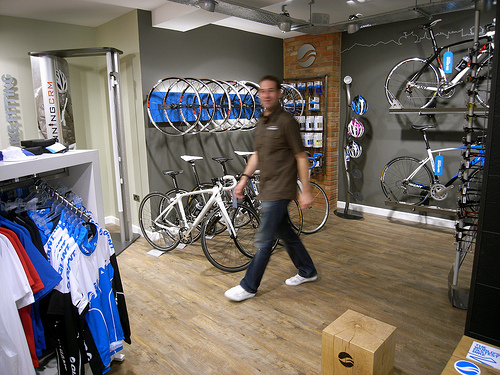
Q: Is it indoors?
A: Yes, it is indoors.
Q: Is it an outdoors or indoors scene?
A: It is indoors.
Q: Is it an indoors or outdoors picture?
A: It is indoors.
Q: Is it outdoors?
A: No, it is indoors.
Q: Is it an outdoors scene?
A: No, it is indoors.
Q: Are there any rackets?
A: No, there are no rackets.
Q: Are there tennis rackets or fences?
A: No, there are no tennis rackets or fences.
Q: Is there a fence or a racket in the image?
A: No, there are no rackets or fences.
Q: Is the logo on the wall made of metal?
A: Yes, the logo is made of metal.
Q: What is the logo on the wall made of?
A: The logo is made of metal.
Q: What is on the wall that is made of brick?
A: The logo is on the wall.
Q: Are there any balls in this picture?
A: No, there are no balls.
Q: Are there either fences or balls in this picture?
A: No, there are no balls or fences.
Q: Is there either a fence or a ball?
A: No, there are no balls or fences.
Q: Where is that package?
A: The package is on the floor.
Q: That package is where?
A: The package is on the floor.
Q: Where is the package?
A: The package is on the floor.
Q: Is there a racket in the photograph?
A: No, there are no rackets.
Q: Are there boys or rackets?
A: No, there are no rackets or boys.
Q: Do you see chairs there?
A: No, there are no chairs.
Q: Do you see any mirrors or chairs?
A: No, there are no chairs or mirrors.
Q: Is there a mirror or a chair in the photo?
A: No, there are no chairs or mirrors.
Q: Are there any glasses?
A: No, there are no glasses.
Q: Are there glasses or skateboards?
A: No, there are no glasses or skateboards.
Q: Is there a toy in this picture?
A: Yes, there is a toy.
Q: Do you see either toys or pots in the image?
A: Yes, there is a toy.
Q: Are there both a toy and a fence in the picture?
A: No, there is a toy but no fences.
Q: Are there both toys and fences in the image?
A: No, there is a toy but no fences.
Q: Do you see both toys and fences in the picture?
A: No, there is a toy but no fences.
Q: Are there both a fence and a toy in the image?
A: No, there is a toy but no fences.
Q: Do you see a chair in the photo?
A: No, there are no chairs.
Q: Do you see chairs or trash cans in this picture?
A: No, there are no chairs or trash cans.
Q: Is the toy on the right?
A: Yes, the toy is on the right of the image.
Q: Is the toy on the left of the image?
A: No, the toy is on the right of the image.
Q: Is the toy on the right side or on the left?
A: The toy is on the right of the image.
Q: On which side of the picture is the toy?
A: The toy is on the right of the image.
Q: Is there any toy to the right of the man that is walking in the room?
A: Yes, there is a toy to the right of the man.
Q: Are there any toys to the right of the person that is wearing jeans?
A: Yes, there is a toy to the right of the man.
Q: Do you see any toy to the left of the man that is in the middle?
A: No, the toy is to the right of the man.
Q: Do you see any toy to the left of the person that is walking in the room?
A: No, the toy is to the right of the man.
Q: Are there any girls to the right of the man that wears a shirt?
A: No, there is a toy to the right of the man.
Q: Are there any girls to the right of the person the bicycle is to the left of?
A: No, there is a toy to the right of the man.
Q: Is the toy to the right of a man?
A: Yes, the toy is to the right of a man.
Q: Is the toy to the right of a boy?
A: No, the toy is to the right of a man.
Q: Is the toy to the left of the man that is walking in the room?
A: No, the toy is to the right of the man.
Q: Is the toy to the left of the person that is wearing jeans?
A: No, the toy is to the right of the man.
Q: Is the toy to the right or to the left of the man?
A: The toy is to the right of the man.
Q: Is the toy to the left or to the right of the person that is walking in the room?
A: The toy is to the right of the man.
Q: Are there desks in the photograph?
A: No, there are no desks.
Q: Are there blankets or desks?
A: No, there are no desks or blankets.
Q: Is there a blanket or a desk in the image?
A: No, there are no desks or blankets.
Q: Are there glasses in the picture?
A: No, there are no glasses.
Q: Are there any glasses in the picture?
A: No, there are no glasses.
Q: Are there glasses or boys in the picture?
A: No, there are no glasses or boys.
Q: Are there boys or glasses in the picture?
A: No, there are no glasses or boys.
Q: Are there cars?
A: No, there are no cars.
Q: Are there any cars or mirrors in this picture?
A: No, there are no cars or mirrors.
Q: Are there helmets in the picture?
A: Yes, there is a helmet.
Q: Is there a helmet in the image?
A: Yes, there is a helmet.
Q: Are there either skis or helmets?
A: Yes, there is a helmet.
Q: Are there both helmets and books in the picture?
A: No, there is a helmet but no books.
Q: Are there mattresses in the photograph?
A: No, there are no mattresses.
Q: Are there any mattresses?
A: No, there are no mattresses.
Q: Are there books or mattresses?
A: No, there are no mattresses or books.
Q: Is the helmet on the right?
A: Yes, the helmet is on the right of the image.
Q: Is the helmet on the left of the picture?
A: No, the helmet is on the right of the image.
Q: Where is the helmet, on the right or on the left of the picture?
A: The helmet is on the right of the image.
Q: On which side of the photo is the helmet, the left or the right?
A: The helmet is on the right of the image.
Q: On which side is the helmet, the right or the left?
A: The helmet is on the right of the image.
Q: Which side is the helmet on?
A: The helmet is on the right of the image.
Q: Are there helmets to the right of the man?
A: Yes, there is a helmet to the right of the man.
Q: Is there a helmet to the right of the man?
A: Yes, there is a helmet to the right of the man.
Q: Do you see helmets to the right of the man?
A: Yes, there is a helmet to the right of the man.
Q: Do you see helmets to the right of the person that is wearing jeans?
A: Yes, there is a helmet to the right of the man.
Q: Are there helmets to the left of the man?
A: No, the helmet is to the right of the man.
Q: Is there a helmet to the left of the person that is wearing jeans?
A: No, the helmet is to the right of the man.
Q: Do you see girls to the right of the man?
A: No, there is a helmet to the right of the man.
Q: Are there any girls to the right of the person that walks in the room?
A: No, there is a helmet to the right of the man.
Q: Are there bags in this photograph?
A: No, there are no bags.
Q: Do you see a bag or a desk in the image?
A: No, there are no bags or desks.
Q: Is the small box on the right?
A: Yes, the box is on the right of the image.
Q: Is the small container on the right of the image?
A: Yes, the box is on the right of the image.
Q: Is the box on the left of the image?
A: No, the box is on the right of the image.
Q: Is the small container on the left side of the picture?
A: No, the box is on the right of the image.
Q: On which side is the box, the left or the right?
A: The box is on the right of the image.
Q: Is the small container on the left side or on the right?
A: The box is on the right of the image.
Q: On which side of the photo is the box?
A: The box is on the right of the image.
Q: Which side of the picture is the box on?
A: The box is on the right of the image.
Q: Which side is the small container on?
A: The box is on the right of the image.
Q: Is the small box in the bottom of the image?
A: Yes, the box is in the bottom of the image.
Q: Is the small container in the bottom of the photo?
A: Yes, the box is in the bottom of the image.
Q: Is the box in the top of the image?
A: No, the box is in the bottom of the image.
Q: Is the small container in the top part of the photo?
A: No, the box is in the bottom of the image.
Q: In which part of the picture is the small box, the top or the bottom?
A: The box is in the bottom of the image.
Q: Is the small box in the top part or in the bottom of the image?
A: The box is in the bottom of the image.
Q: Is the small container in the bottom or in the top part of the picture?
A: The box is in the bottom of the image.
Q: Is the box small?
A: Yes, the box is small.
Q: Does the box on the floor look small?
A: Yes, the box is small.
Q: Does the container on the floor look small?
A: Yes, the box is small.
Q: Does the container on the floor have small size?
A: Yes, the box is small.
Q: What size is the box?
A: The box is small.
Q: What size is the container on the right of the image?
A: The box is small.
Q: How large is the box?
A: The box is small.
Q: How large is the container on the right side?
A: The box is small.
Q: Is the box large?
A: No, the box is small.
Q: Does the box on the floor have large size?
A: No, the box is small.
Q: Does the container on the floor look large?
A: No, the box is small.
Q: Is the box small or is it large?
A: The box is small.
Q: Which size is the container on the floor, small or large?
A: The box is small.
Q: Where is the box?
A: The box is on the floor.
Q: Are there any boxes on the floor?
A: Yes, there is a box on the floor.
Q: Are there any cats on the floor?
A: No, there is a box on the floor.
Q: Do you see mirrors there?
A: No, there are no mirrors.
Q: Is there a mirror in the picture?
A: No, there are no mirrors.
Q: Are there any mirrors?
A: No, there are no mirrors.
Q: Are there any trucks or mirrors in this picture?
A: No, there are no mirrors or trucks.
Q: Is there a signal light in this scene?
A: No, there are no traffic lights.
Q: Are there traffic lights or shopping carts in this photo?
A: No, there are no traffic lights or shopping carts.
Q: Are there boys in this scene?
A: No, there are no boys.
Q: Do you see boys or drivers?
A: No, there are no boys or drivers.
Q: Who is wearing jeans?
A: The man is wearing jeans.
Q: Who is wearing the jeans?
A: The man is wearing jeans.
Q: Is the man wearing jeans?
A: Yes, the man is wearing jeans.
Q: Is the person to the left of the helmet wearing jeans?
A: Yes, the man is wearing jeans.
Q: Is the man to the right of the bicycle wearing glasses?
A: No, the man is wearing jeans.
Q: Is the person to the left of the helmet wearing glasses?
A: No, the man is wearing jeans.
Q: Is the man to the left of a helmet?
A: Yes, the man is to the left of a helmet.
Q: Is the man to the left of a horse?
A: No, the man is to the left of a helmet.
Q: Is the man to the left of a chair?
A: No, the man is to the left of a helmet.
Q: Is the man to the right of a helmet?
A: No, the man is to the left of a helmet.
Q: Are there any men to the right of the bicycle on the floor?
A: Yes, there is a man to the right of the bicycle.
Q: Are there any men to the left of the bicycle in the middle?
A: No, the man is to the right of the bicycle.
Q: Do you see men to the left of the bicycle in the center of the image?
A: No, the man is to the right of the bicycle.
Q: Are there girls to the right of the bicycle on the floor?
A: No, there is a man to the right of the bicycle.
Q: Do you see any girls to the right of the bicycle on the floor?
A: No, there is a man to the right of the bicycle.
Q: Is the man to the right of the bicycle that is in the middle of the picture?
A: Yes, the man is to the right of the bicycle.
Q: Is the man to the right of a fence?
A: No, the man is to the right of the bicycle.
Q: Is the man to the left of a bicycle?
A: No, the man is to the right of a bicycle.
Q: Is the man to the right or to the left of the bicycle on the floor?
A: The man is to the right of the bicycle.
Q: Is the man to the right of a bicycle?
A: No, the man is to the left of a bicycle.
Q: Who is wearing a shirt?
A: The man is wearing a shirt.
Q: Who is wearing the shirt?
A: The man is wearing a shirt.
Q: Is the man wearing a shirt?
A: Yes, the man is wearing a shirt.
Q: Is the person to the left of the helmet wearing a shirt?
A: Yes, the man is wearing a shirt.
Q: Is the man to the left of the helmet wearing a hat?
A: No, the man is wearing a shirt.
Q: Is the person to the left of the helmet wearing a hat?
A: No, the man is wearing a shirt.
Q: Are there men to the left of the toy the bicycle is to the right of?
A: Yes, there is a man to the left of the toy.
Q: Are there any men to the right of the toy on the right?
A: No, the man is to the left of the toy.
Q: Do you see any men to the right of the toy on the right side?
A: No, the man is to the left of the toy.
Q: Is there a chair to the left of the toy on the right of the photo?
A: No, there is a man to the left of the toy.